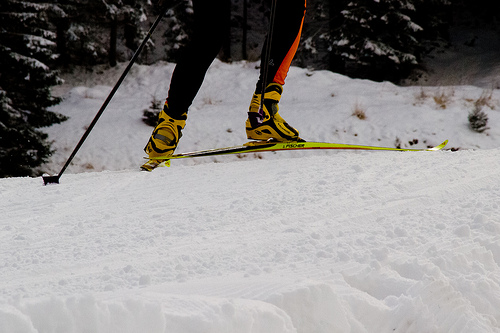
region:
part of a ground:
[265, 202, 317, 266]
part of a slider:
[302, 134, 341, 178]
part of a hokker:
[47, 73, 154, 229]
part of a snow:
[258, 207, 310, 290]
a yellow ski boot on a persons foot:
[140, 107, 187, 162]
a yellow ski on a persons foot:
[174, 142, 454, 161]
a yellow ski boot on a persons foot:
[245, 79, 302, 144]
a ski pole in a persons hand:
[40, 1, 176, 188]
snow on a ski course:
[3, 150, 495, 329]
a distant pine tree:
[296, 0, 428, 81]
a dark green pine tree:
[0, 0, 66, 174]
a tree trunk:
[106, 0, 120, 61]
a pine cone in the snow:
[468, 113, 490, 135]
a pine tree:
[34, 0, 104, 74]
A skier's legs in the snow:
[20, 0, 455, 222]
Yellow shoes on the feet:
[254, 80, 309, 165]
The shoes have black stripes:
[245, 111, 290, 143]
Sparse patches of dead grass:
[408, 84, 476, 119]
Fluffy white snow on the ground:
[123, 185, 344, 312]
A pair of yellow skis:
[137, 131, 448, 178]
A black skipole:
[18, 22, 167, 187]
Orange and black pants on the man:
[248, 4, 316, 88]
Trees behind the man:
[8, 33, 68, 158]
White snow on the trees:
[17, 29, 54, 77]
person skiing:
[37, 14, 472, 219]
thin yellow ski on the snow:
[154, 130, 466, 162]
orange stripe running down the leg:
[272, 7, 307, 92]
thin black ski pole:
[34, 27, 154, 196]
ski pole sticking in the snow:
[40, 27, 165, 194]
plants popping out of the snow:
[409, 73, 454, 107]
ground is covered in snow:
[4, 77, 490, 328]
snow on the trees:
[16, 25, 57, 52]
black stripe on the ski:
[192, 135, 288, 156]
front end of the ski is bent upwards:
[433, 132, 457, 152]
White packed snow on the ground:
[373, 196, 449, 246]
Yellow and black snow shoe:
[247, 94, 295, 136]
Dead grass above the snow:
[418, 85, 499, 127]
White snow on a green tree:
[0, 53, 48, 146]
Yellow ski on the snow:
[226, 142, 388, 152]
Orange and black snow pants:
[256, 11, 304, 85]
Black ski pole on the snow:
[38, 73, 123, 185]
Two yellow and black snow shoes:
[143, 94, 290, 156]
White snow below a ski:
[193, 167, 453, 187]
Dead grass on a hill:
[326, 86, 489, 132]